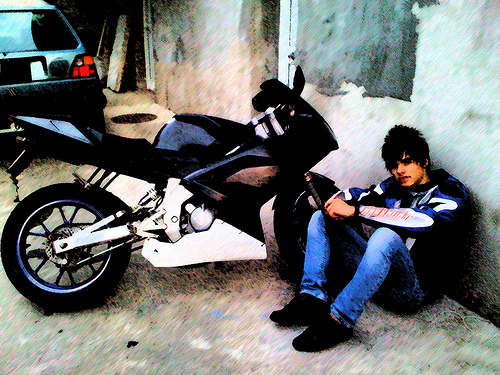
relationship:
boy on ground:
[296, 123, 445, 373] [146, 301, 263, 363]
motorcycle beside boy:
[10, 70, 332, 317] [296, 123, 445, 373]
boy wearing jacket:
[296, 123, 445, 373] [342, 168, 457, 284]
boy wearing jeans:
[296, 123, 445, 373] [287, 204, 427, 328]